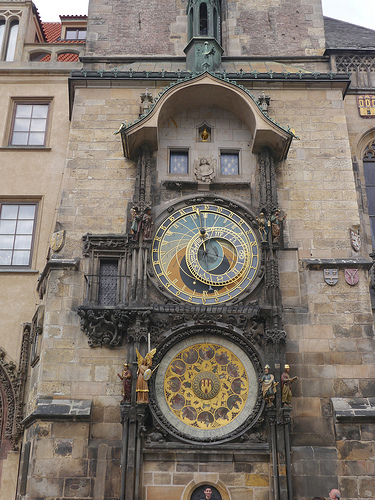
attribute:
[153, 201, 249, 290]
clock face — fancy, ornate, round, large, circular, medieval, black, gold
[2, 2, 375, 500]
building — brick, stone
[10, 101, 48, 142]
window — rose style, rectangular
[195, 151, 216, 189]
statue — an angel, angel, small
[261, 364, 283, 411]
statue — a man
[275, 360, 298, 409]
statue — a man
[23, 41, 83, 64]
balcony — small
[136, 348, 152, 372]
wings — golden, large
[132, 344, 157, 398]
statue — an angel, gold, angel, golden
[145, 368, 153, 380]
shield — round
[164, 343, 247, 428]
artwork — gold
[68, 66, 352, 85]
ledge — stone, decorative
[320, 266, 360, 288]
shields — carved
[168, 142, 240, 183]
windows — small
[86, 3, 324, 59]
brick — worn out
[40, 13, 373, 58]
roof — tile, brown, red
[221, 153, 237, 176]
window — star patterned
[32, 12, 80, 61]
roof — slate